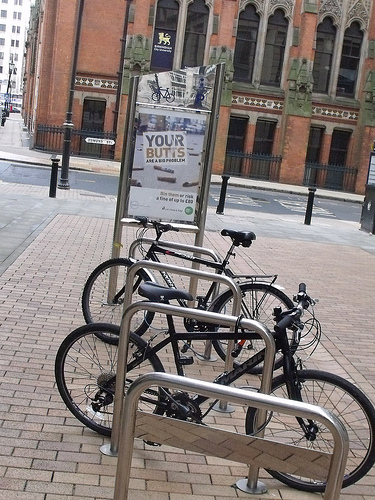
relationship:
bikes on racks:
[46, 228, 374, 499] [118, 236, 292, 484]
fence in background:
[42, 143, 329, 220] [3, 82, 364, 207]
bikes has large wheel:
[54, 282, 373, 499] [49, 316, 177, 441]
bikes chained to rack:
[54, 282, 373, 499] [111, 298, 287, 386]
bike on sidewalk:
[78, 218, 319, 328] [46, 228, 374, 499]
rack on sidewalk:
[111, 298, 287, 386] [46, 228, 374, 499]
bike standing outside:
[78, 218, 319, 328] [6, 10, 374, 496]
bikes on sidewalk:
[54, 282, 373, 499] [46, 228, 374, 499]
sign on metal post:
[118, 60, 223, 227] [101, 54, 235, 307]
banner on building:
[151, 20, 181, 68] [25, 0, 373, 201]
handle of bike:
[265, 307, 302, 335] [74, 208, 306, 375]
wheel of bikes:
[49, 316, 177, 441] [54, 282, 373, 499]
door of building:
[74, 90, 110, 156] [25, 0, 373, 201]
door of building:
[298, 114, 324, 190] [25, 0, 373, 201]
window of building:
[335, 17, 367, 105] [25, 0, 373, 201]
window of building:
[308, 10, 338, 100] [25, 0, 373, 201]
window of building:
[258, 6, 295, 91] [25, 0, 373, 201]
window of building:
[228, 2, 264, 87] [25, 0, 373, 201]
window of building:
[177, 4, 217, 67] [25, 0, 373, 201]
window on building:
[258, 6, 295, 91] [25, 0, 373, 201]